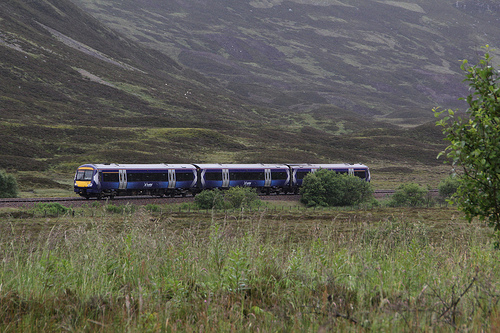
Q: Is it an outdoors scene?
A: Yes, it is outdoors.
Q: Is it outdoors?
A: Yes, it is outdoors.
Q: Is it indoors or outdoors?
A: It is outdoors.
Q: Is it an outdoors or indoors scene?
A: It is outdoors.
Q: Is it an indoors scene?
A: No, it is outdoors.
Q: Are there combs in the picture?
A: No, there are no combs.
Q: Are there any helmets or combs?
A: No, there are no combs or helmets.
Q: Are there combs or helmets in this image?
A: No, there are no combs or helmets.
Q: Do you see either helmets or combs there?
A: No, there are no combs or helmets.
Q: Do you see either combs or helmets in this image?
A: No, there are no combs or helmets.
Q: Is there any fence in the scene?
A: No, there are no fences.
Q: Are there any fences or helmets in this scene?
A: No, there are no fences or helmets.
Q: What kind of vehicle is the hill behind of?
A: The hill is behind the train.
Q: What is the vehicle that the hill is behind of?
A: The vehicle is a train.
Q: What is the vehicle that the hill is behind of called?
A: The vehicle is a train.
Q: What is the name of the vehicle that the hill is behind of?
A: The vehicle is a train.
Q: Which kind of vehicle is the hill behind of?
A: The hill is behind the train.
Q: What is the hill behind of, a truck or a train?
A: The hill is behind a train.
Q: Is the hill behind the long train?
A: Yes, the hill is behind the train.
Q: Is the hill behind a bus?
A: No, the hill is behind the train.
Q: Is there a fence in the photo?
A: No, there are no fences.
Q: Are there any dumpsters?
A: No, there are no dumpsters.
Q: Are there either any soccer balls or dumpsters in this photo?
A: No, there are no dumpsters or soccer balls.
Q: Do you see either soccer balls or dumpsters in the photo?
A: No, there are no dumpsters or soccer balls.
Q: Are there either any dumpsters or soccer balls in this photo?
A: No, there are no dumpsters or soccer balls.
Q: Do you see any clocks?
A: No, there are no clocks.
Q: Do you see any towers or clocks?
A: No, there are no clocks or towers.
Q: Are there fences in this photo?
A: No, there are no fences.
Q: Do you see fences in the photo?
A: No, there are no fences.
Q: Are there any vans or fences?
A: No, there are no fences or vans.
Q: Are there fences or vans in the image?
A: No, there are no fences or vans.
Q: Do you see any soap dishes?
A: No, there are no soap dishes.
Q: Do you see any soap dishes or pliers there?
A: No, there are no soap dishes or pliers.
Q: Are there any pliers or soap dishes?
A: No, there are no soap dishes or pliers.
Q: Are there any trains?
A: Yes, there is a train.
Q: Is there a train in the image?
A: Yes, there is a train.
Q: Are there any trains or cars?
A: Yes, there is a train.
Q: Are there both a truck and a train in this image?
A: No, there is a train but no trucks.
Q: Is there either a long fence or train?
A: Yes, there is a long train.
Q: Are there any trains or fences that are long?
A: Yes, the train is long.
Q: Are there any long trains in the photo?
A: Yes, there is a long train.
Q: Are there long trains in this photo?
A: Yes, there is a long train.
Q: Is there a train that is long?
A: Yes, there is a train that is long.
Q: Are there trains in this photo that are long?
A: Yes, there is a train that is long.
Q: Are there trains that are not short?
A: Yes, there is a long train.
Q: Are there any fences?
A: No, there are no fences.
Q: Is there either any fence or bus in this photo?
A: No, there are no fences or buses.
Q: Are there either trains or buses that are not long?
A: No, there is a train but it is long.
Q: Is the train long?
A: Yes, the train is long.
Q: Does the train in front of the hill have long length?
A: Yes, the train is long.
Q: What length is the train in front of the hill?
A: The train is long.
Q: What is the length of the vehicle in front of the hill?
A: The train is long.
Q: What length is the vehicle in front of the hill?
A: The train is long.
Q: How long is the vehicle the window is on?
A: The train is long.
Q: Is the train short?
A: No, the train is long.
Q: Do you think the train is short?
A: No, the train is long.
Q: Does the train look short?
A: No, the train is long.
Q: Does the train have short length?
A: No, the train is long.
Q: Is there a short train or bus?
A: No, there is a train but it is long.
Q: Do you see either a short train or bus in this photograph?
A: No, there is a train but it is long.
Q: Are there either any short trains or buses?
A: No, there is a train but it is long.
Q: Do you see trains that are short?
A: No, there is a train but it is long.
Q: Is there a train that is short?
A: No, there is a train but it is long.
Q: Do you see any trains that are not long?
A: No, there is a train but it is long.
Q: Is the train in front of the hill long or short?
A: The train is long.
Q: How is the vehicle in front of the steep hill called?
A: The vehicle is a train.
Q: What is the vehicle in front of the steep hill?
A: The vehicle is a train.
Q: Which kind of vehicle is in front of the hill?
A: The vehicle is a train.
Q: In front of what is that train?
A: The train is in front of the hill.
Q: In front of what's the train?
A: The train is in front of the hill.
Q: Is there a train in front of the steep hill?
A: Yes, there is a train in front of the hill.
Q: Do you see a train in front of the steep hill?
A: Yes, there is a train in front of the hill.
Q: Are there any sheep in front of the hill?
A: No, there is a train in front of the hill.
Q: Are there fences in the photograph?
A: No, there are no fences.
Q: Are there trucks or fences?
A: No, there are no fences or trucks.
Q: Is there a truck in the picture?
A: No, there are no trucks.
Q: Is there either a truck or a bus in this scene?
A: No, there are no trucks or buses.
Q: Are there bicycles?
A: No, there are no bicycles.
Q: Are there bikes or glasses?
A: No, there are no bikes or glasses.